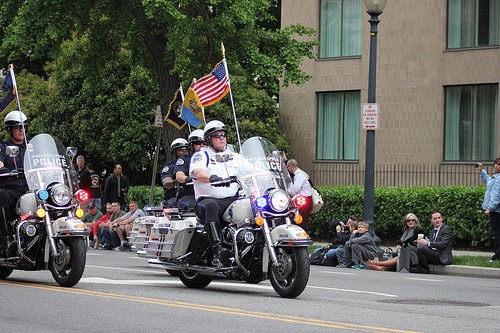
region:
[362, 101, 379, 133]
A street sign.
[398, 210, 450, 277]
A couple sit on the curb.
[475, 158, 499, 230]
A person takes a picture.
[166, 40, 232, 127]
Flags wave off the bike.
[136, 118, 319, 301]
The police ride their bikes in a parade.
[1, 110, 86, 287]
A bike policeman rides in a parade.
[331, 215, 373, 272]
The kids sit on the curb.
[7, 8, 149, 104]
A tree stands tall.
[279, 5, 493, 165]
A building in the background.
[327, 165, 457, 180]
A steel fence.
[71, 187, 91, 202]
red motorcycle light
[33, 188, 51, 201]
blue motorcycle light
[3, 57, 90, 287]
police officer riding a motorcycle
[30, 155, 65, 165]
white print on a motorcycle reading Police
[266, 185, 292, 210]
round white motorcycle light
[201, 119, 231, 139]
white and black motorcycle helmet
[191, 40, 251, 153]
USA flag on a motorcycle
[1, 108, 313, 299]
police officers riding motorcycles on a street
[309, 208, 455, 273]
people seating on a curb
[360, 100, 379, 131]
red and white sign on a pole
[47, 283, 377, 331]
yellow lines in the street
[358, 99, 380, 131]
red and white street sign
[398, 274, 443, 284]
white line in the street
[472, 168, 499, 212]
man wearing a blue long sleeve shirt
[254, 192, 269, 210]
blue light on the motorcycle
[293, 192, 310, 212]
red light on the motorcycle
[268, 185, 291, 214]
white headlight on the motorcycle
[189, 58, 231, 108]
red, white and blue flag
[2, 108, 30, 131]
white and black helmet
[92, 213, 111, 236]
man wearing a red shirt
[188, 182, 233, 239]
he is riding the bike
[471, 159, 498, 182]
the person is holding a camera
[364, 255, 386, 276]
she has no shoes on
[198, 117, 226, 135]
the helmet is white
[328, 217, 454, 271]
they are sitting on the curb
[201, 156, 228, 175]
the shirt is white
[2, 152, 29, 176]
the shirt is black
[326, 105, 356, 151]
the blind is closed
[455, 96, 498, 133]
the blind is open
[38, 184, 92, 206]
the lights are on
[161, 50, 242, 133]
the flags waving in the wind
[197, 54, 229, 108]
the american flag on the pole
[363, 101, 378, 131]
the white sign on the pole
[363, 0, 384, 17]
the round street lamp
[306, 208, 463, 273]
the people sitting on the curb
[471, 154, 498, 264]
the person taking a picture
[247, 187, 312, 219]
the flashing police lights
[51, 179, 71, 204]
the headlight on the bike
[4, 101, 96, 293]
the motorcycle on the road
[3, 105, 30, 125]
the white helmet on the police officer